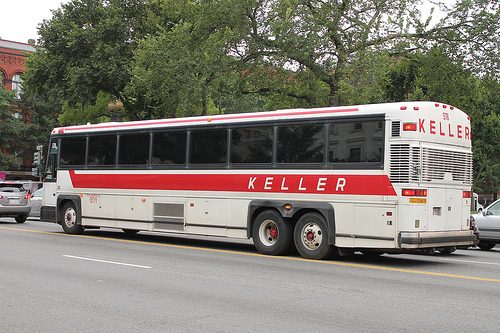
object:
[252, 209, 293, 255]
black wheel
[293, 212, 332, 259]
black wheel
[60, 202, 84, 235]
black wheel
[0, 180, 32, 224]
car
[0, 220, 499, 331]
pavement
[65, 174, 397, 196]
red stripe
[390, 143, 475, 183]
vents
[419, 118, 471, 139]
keller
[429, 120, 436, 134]
red letter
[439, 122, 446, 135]
red letter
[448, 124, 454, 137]
red letter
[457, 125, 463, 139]
red letter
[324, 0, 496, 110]
trees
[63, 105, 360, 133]
stripe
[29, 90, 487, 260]
silver spoon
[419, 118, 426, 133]
k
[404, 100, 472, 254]
back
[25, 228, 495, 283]
line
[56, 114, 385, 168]
passenger windows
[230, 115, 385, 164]
reflection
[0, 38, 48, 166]
brick building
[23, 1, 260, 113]
trees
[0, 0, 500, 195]
park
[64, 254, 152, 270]
line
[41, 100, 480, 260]
bus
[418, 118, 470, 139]
letters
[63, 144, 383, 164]
passengers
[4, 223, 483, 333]
route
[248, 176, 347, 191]
company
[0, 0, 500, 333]
city